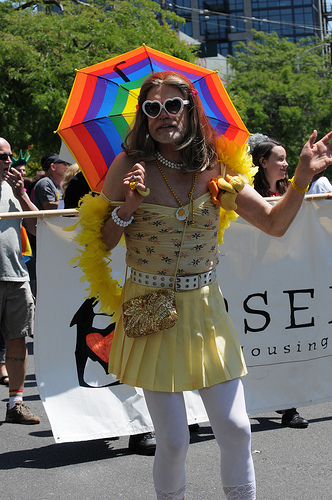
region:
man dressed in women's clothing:
[56, 42, 318, 497]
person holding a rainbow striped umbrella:
[53, 40, 323, 473]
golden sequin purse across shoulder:
[119, 145, 197, 340]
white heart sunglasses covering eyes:
[140, 96, 193, 118]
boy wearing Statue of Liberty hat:
[7, 147, 32, 181]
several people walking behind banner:
[1, 132, 326, 436]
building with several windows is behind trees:
[2, 1, 331, 97]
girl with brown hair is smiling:
[252, 139, 291, 206]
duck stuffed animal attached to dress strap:
[205, 172, 247, 214]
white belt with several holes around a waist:
[123, 263, 217, 292]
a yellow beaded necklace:
[160, 161, 205, 225]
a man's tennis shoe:
[2, 400, 41, 426]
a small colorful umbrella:
[53, 38, 253, 196]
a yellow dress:
[102, 199, 249, 392]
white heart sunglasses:
[136, 96, 191, 118]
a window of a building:
[281, 9, 292, 35]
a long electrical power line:
[178, 3, 321, 35]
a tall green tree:
[215, 27, 330, 162]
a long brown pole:
[0, 209, 79, 218]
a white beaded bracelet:
[111, 204, 135, 228]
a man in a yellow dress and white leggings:
[77, 68, 328, 497]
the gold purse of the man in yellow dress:
[120, 286, 174, 333]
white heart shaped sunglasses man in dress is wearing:
[141, 96, 184, 117]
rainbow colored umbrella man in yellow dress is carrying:
[54, 43, 252, 195]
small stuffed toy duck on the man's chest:
[210, 173, 248, 212]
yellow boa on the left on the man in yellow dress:
[78, 195, 119, 323]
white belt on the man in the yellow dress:
[130, 267, 217, 289]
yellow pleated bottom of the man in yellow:
[110, 287, 248, 390]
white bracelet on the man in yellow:
[111, 207, 134, 227]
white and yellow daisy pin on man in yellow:
[173, 205, 190, 221]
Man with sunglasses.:
[117, 71, 312, 191]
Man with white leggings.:
[90, 373, 296, 493]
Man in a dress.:
[98, 53, 324, 307]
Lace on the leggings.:
[143, 468, 209, 495]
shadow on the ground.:
[61, 416, 166, 471]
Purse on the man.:
[39, 229, 240, 419]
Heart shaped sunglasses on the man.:
[120, 70, 216, 136]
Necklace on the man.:
[124, 149, 224, 242]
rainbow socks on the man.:
[6, 378, 45, 417]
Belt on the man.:
[89, 173, 247, 304]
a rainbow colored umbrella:
[66, 44, 272, 184]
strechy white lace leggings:
[123, 364, 271, 498]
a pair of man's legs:
[124, 376, 271, 499]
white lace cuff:
[218, 482, 263, 498]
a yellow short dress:
[97, 184, 262, 392]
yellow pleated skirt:
[104, 297, 260, 389]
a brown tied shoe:
[1, 396, 40, 424]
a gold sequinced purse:
[119, 290, 185, 339]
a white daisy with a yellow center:
[172, 204, 185, 217]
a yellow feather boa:
[68, 178, 235, 308]